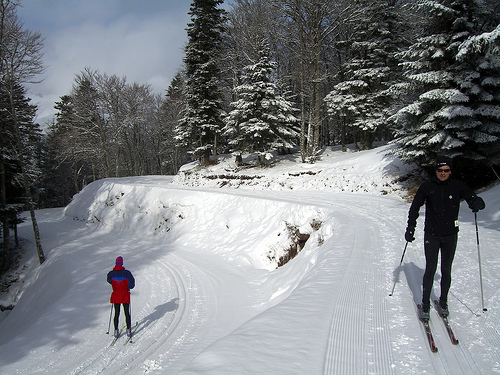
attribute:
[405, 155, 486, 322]
man — skiing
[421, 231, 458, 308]
pants — black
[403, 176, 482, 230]
jacket — black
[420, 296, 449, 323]
boots — black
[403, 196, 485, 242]
gloves — black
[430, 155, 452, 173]
hat — black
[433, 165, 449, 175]
glasses — black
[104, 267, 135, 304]
coat — red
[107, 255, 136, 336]
person — skiing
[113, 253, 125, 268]
hat — red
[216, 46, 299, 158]
tree — green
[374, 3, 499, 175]
tree — green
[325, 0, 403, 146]
tree — green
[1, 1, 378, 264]
trees — bare, tall, brown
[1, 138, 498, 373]
snow — white, thick